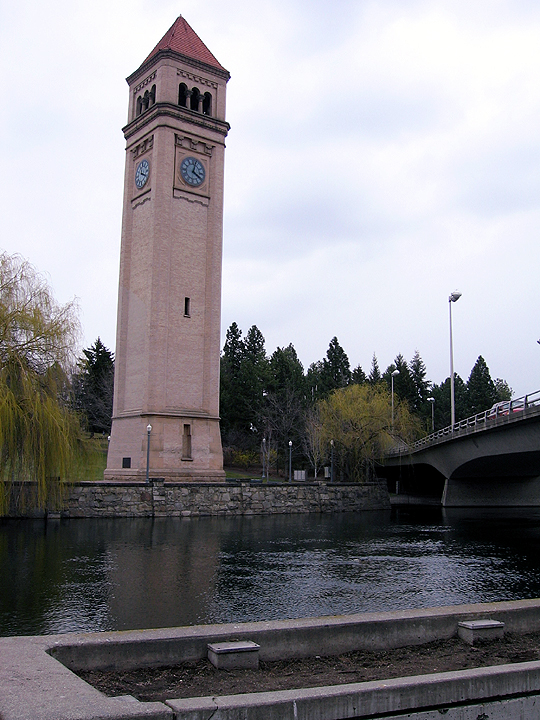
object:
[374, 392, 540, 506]
bridge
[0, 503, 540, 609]
water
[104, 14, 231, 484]
tower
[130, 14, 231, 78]
roof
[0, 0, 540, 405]
clouds